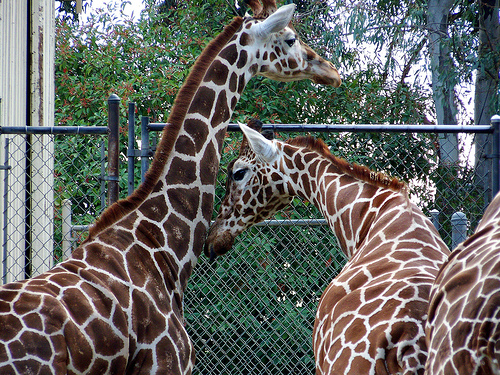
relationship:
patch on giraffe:
[369, 205, 420, 245] [145, 3, 354, 143]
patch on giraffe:
[313, 342, 328, 366] [201, 122, 426, 374]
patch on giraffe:
[291, 154, 325, 200] [201, 122, 426, 374]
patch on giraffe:
[127, 240, 174, 314] [2, 0, 341, 374]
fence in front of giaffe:
[1, 89, 498, 374] [198, 112, 460, 370]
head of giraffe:
[226, 1, 346, 91] [222, 14, 347, 125]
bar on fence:
[138, 123, 499, 132] [1, 89, 498, 374]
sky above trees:
[386, 25, 448, 85] [51, 3, 434, 373]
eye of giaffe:
[229, 164, 249, 183] [198, 112, 460, 370]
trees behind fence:
[62, 41, 132, 178] [4, 102, 496, 356]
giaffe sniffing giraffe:
[198, 112, 460, 370] [2, 0, 341, 374]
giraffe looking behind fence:
[2, 0, 341, 374] [1, 89, 498, 374]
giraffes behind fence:
[2, 4, 484, 363] [1, 89, 498, 374]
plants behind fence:
[44, 0, 498, 375] [1, 89, 498, 374]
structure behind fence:
[12, 24, 84, 284] [48, 107, 475, 371]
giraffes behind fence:
[2, 4, 484, 363] [229, 230, 296, 300]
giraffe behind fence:
[2, 0, 341, 374] [1, 89, 498, 374]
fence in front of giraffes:
[1, 89, 498, 374] [2, 4, 484, 363]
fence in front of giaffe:
[1, 89, 498, 374] [122, 5, 488, 347]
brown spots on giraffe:
[92, 221, 184, 338] [108, 0, 407, 371]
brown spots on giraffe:
[346, 268, 417, 350] [108, 0, 407, 371]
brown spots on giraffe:
[450, 267, 499, 346] [108, 0, 407, 371]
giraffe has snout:
[2, 0, 341, 374] [276, 22, 360, 104]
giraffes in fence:
[2, 4, 484, 363] [1, 89, 498, 374]